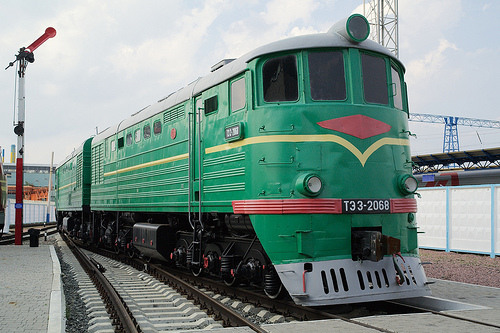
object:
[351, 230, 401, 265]
coupler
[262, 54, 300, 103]
window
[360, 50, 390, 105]
window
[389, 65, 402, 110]
window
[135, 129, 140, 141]
window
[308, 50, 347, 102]
window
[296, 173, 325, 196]
headlight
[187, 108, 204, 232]
rails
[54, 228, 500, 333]
rails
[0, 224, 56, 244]
rails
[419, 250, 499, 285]
ground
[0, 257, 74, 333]
ground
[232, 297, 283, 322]
ground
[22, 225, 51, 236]
ground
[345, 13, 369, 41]
light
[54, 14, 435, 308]
green train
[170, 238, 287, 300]
wheels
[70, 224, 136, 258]
wheels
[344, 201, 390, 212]
writing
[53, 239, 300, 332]
tracks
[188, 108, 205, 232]
hand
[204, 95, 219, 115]
window